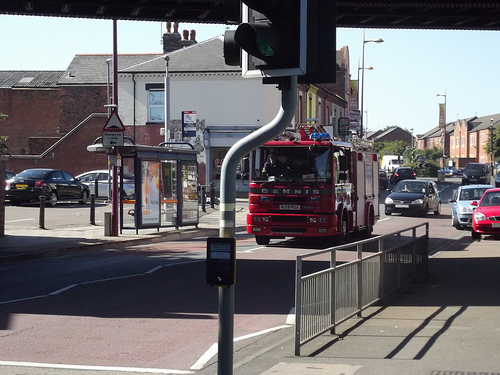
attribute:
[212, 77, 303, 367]
pole — metal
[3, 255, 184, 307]
lines — white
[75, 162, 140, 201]
car — white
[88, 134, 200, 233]
bus stop — long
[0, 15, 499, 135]
sky — sunny, blue, cloudless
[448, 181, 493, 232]
car — silver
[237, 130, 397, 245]
bus — red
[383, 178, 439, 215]
car — black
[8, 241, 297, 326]
line — zigzags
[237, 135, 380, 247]
fire truck — red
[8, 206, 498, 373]
street — gray